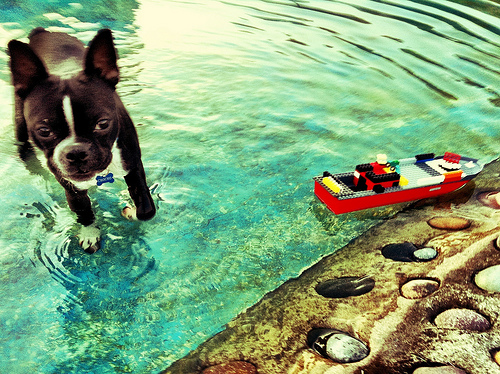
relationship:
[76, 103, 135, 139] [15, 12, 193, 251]
eye of dog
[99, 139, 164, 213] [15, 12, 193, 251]
leg of dog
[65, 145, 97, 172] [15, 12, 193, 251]
nose of dog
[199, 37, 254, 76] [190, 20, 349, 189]
light in water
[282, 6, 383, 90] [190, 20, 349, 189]
ripple in water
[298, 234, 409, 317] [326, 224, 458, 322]
rock on land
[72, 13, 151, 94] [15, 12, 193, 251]
ear of dog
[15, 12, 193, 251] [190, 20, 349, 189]
dog in water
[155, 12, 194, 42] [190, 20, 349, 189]
sun on water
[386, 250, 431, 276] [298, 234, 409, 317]
stone in rock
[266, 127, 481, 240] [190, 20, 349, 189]
boat in water